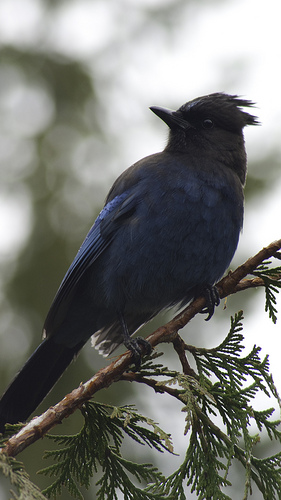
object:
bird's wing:
[39, 176, 155, 339]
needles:
[112, 404, 173, 456]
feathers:
[162, 171, 225, 225]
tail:
[0, 333, 75, 435]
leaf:
[229, 317, 243, 345]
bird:
[0, 92, 262, 434]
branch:
[211, 267, 248, 298]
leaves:
[168, 363, 280, 498]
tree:
[0, 227, 281, 500]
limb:
[0, 238, 281, 459]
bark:
[90, 371, 104, 382]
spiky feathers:
[223, 92, 260, 131]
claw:
[194, 284, 220, 324]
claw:
[122, 328, 151, 366]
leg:
[117, 307, 129, 337]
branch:
[54, 353, 142, 401]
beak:
[147, 104, 174, 131]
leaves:
[81, 426, 152, 495]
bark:
[65, 391, 75, 406]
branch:
[0, 391, 49, 442]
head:
[149, 92, 261, 187]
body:
[100, 155, 244, 322]